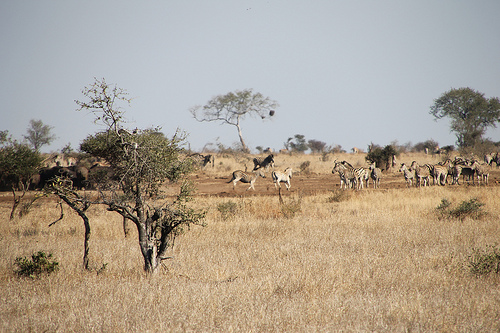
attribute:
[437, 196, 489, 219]
bush — green, brown, small, leafy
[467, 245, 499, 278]
bush — green, brown, small, leafy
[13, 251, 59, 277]
bush — green, brown, small, leafy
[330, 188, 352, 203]
bush — green, brown, small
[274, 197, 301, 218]
bush — green, brown, small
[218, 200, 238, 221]
bush — green, brown, small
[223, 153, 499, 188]
animals — running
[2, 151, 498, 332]
ground — dirt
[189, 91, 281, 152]
tree — tall, bare, brown, dead, dry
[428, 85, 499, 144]
tree — tall, green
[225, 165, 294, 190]
animals — running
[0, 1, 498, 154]
sky — clear, grey, greyish blue, hazy, bluish, gray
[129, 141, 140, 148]
nest — brown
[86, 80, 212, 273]
tree — barrren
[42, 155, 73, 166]
rock formation — brown, dark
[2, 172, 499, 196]
trail — dirt